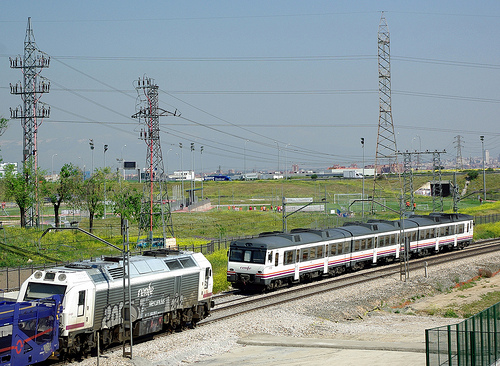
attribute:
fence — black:
[423, 316, 483, 360]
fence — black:
[423, 307, 499, 357]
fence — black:
[417, 307, 498, 362]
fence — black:
[421, 317, 496, 361]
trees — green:
[9, 162, 186, 224]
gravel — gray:
[248, 308, 275, 324]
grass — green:
[88, 210, 276, 269]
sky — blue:
[50, 17, 492, 146]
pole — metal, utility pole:
[134, 79, 179, 279]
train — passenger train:
[229, 210, 497, 297]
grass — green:
[176, 206, 316, 252]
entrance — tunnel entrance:
[422, 175, 460, 201]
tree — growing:
[5, 161, 38, 239]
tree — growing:
[35, 155, 83, 255]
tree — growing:
[71, 167, 106, 235]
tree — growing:
[114, 174, 168, 240]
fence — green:
[428, 309, 499, 362]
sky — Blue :
[159, 24, 360, 69]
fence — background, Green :
[7, 230, 84, 257]